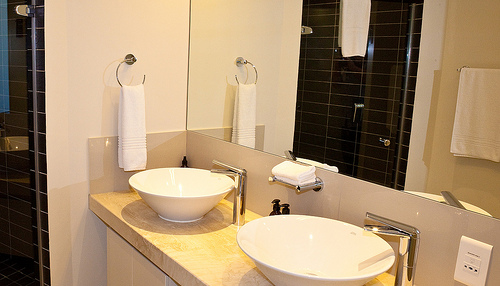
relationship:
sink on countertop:
[236, 212, 396, 285] [91, 186, 422, 283]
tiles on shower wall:
[0, 1, 53, 281] [28, 2, 204, 283]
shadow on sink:
[129, 199, 234, 239] [112, 150, 215, 221]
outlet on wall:
[453, 235, 496, 283] [43, 7, 498, 283]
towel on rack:
[118, 82, 150, 172] [113, 52, 147, 88]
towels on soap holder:
[271, 156, 318, 182] [269, 171, 329, 192]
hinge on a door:
[347, 98, 367, 109] [286, 11, 474, 203]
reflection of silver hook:
[230, 83, 261, 150] [232, 55, 258, 85]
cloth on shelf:
[118, 86, 154, 174] [266, 179, 326, 196]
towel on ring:
[118, 85, 149, 172] [92, 44, 162, 79]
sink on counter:
[236, 210, 397, 284] [182, 222, 234, 284]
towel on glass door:
[328, 3, 393, 75] [296, 3, 426, 170]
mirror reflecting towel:
[188, 0, 497, 214] [106, 73, 152, 168]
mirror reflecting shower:
[188, 0, 497, 214] [0, 2, 52, 283]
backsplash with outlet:
[184, 131, 499, 284] [452, 235, 493, 284]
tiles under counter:
[306, 64, 339, 130] [86, 193, 411, 283]